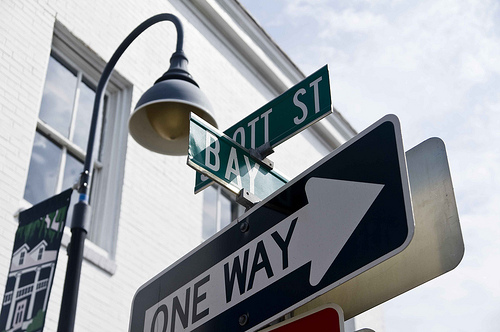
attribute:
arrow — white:
[101, 175, 387, 328]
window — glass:
[16, 10, 176, 275]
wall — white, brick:
[125, 149, 198, 265]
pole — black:
[58, 204, 85, 330]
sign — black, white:
[124, 123, 404, 328]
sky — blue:
[235, 0, 497, 330]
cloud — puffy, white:
[264, 2, 332, 29]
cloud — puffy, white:
[316, 11, 388, 38]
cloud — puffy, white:
[395, 2, 487, 76]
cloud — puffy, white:
[300, 42, 352, 78]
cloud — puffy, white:
[330, 37, 485, 127]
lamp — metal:
[73, 3, 225, 193]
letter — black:
[269, 216, 297, 268]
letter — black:
[246, 238, 273, 289]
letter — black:
[221, 248, 248, 302]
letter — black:
[191, 272, 211, 322]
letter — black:
[168, 285, 190, 330]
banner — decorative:
[0, 174, 89, 319]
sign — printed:
[119, 92, 332, 212]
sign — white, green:
[191, 61, 333, 195]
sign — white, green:
[185, 110, 289, 208]